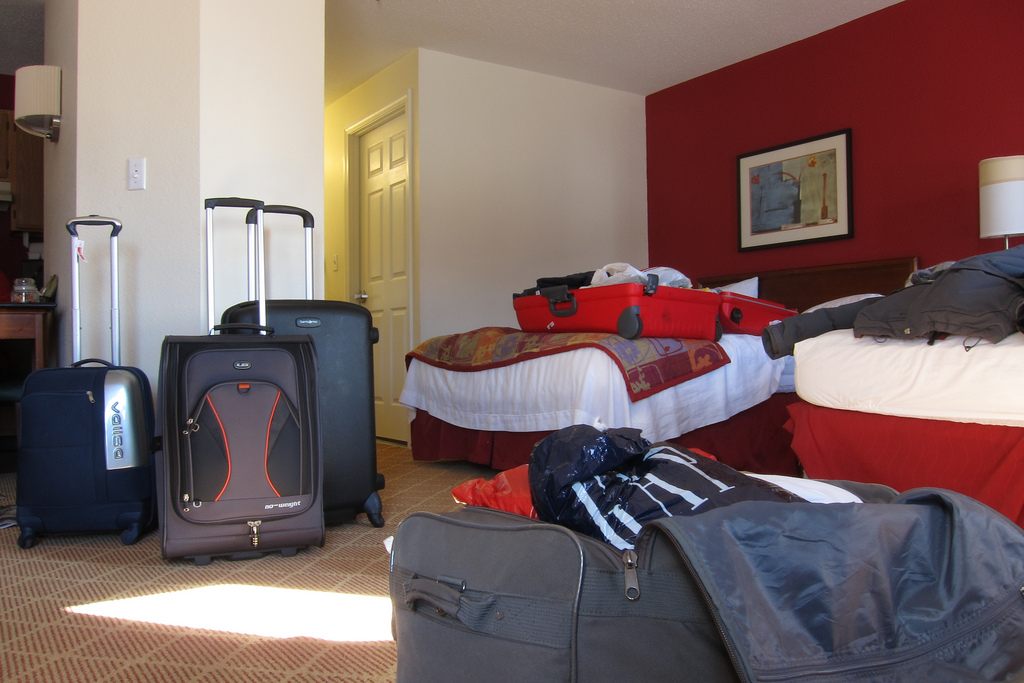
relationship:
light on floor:
[60, 579, 398, 647] [0, 438, 499, 681]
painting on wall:
[736, 128, 852, 254] [646, 3, 1023, 311]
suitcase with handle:
[9, 214, 162, 550] [65, 214, 123, 368]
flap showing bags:
[638, 485, 1023, 682] [662, 488, 1022, 674]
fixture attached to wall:
[13, 63, 64, 144] [42, 4, 78, 376]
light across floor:
[60, 579, 398, 647] [0, 438, 499, 681]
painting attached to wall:
[736, 128, 852, 254] [646, 3, 1023, 311]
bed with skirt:
[409, 329, 795, 476] [412, 392, 797, 476]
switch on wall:
[125, 152, 150, 195] [66, 3, 328, 403]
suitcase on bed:
[509, 289, 802, 336] [409, 329, 795, 476]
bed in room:
[409, 329, 795, 476] [0, 3, 1019, 682]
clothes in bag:
[433, 421, 860, 547] [390, 423, 1021, 677]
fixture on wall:
[13, 63, 64, 144] [42, 4, 78, 376]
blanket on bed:
[407, 326, 730, 404] [409, 329, 795, 476]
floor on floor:
[0, 438, 499, 681] [2, 381, 504, 678]